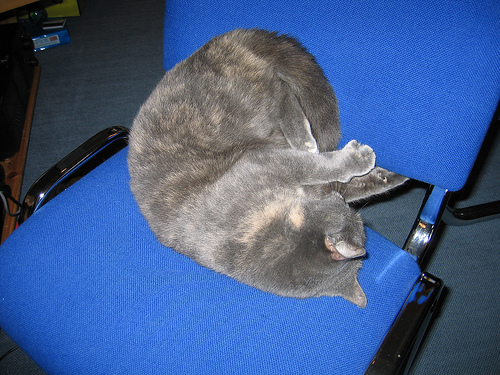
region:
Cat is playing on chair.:
[115, 22, 415, 309]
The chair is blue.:
[2, 2, 495, 374]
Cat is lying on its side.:
[122, 22, 419, 312]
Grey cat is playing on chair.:
[121, 23, 416, 312]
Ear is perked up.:
[122, 22, 413, 309]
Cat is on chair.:
[0, 3, 495, 374]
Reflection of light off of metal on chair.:
[402, 218, 436, 257]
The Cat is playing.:
[121, 25, 414, 309]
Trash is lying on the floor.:
[0, 1, 124, 63]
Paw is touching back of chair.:
[164, 3, 499, 199]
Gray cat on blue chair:
[127, 26, 412, 308]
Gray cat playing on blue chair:
[4, 2, 497, 373]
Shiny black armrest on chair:
[18, 115, 128, 222]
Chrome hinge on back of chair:
[399, 182, 461, 260]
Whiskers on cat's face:
[324, 178, 371, 213]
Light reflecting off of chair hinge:
[402, 178, 453, 264]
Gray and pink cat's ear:
[321, 233, 368, 261]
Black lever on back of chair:
[444, 193, 499, 222]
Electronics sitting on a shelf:
[1, 23, 40, 161]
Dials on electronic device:
[21, 38, 42, 67]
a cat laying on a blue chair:
[116, 60, 413, 312]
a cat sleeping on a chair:
[125, 73, 425, 308]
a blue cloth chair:
[102, 23, 486, 360]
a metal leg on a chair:
[0, 106, 151, 221]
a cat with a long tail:
[254, 27, 360, 156]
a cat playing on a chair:
[100, 44, 417, 311]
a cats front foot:
[313, 134, 381, 184]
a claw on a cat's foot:
[365, 172, 409, 194]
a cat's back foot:
[248, 105, 328, 173]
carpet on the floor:
[43, 32, 161, 125]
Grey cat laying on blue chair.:
[127, 28, 409, 309]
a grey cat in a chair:
[18, 35, 445, 303]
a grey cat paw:
[288, 102, 402, 202]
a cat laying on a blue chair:
[70, 15, 492, 373]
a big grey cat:
[135, 26, 446, 287]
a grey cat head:
[275, 183, 412, 303]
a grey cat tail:
[190, 21, 410, 152]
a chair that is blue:
[52, 2, 497, 357]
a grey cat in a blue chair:
[28, 56, 492, 350]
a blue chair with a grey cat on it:
[41, 19, 491, 366]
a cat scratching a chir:
[188, 46, 489, 268]